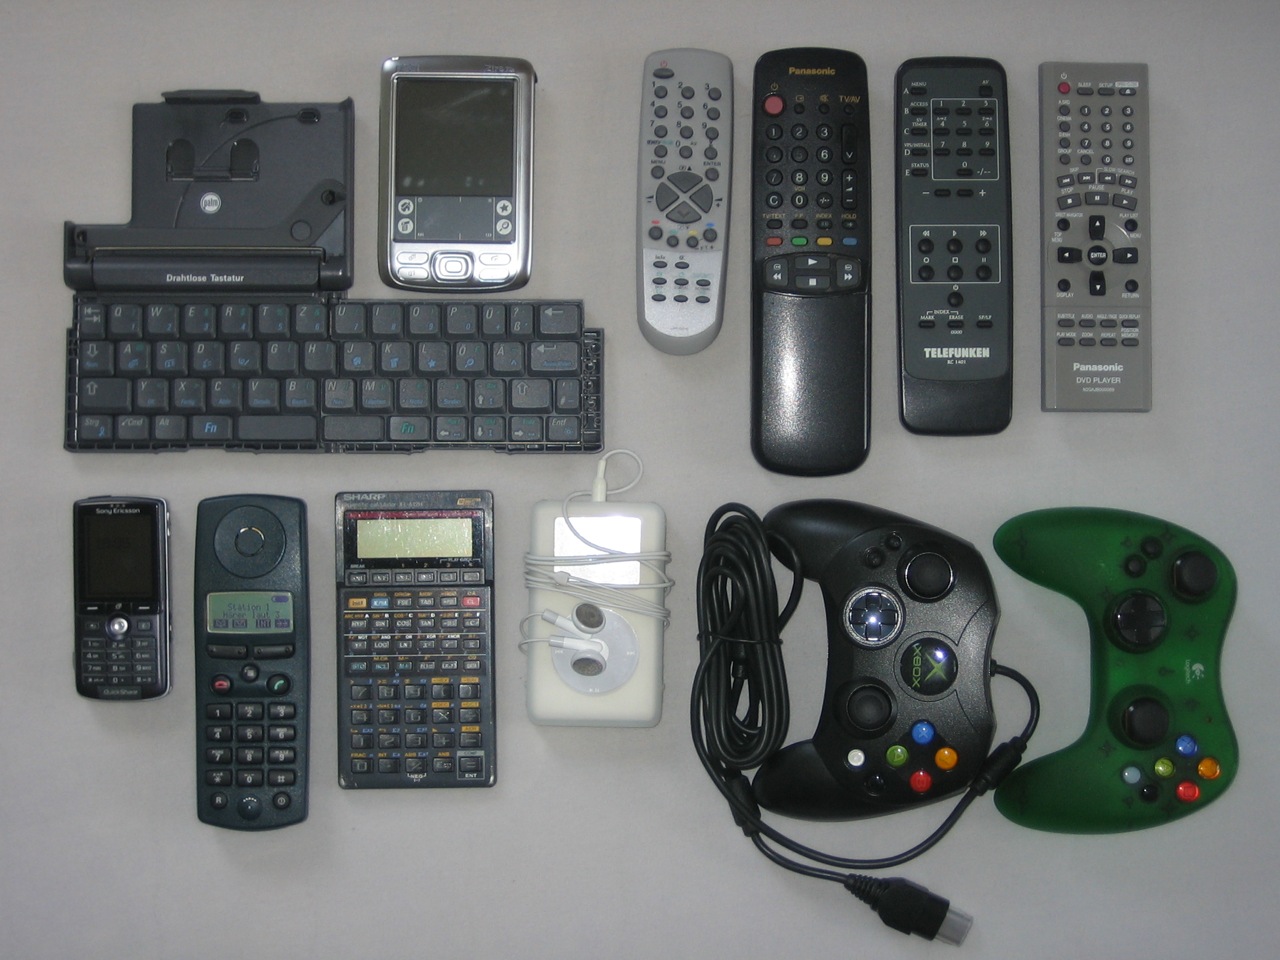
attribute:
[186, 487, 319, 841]
sheep — rectangular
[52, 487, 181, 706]
cell phone — gray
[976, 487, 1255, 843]
jpystick — green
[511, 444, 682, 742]
ipod — small, white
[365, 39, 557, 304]
cellphone — small, gray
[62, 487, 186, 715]
cellphone — small, black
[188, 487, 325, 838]
cellphone — big, black, vintage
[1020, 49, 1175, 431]
remote control — gray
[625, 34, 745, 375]
remote control — gray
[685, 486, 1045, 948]
xbox controller — black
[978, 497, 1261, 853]
xbox controller — green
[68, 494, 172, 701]
cell phone — old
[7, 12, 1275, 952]
table — white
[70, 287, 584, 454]
keyboard — black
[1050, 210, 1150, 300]
keys — black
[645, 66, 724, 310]
keys — gray